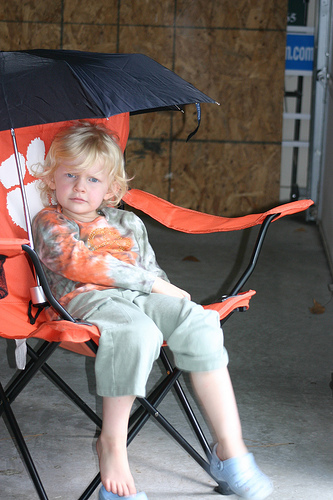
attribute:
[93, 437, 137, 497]
foot — bare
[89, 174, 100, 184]
eye — blue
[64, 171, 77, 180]
eye — blue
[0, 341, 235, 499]
legs — metal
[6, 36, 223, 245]
umbrella — black, open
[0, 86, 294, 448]
chair — folded, orange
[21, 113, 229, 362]
kid — blonde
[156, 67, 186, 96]
wall — brown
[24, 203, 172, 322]
shirt — orange, grey, long-sleeve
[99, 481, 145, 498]
croc — blue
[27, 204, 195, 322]
shirt — orange, gray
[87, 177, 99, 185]
eye — blue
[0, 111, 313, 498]
chair — folding, orange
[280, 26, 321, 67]
sign — blue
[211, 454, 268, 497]
shoe — white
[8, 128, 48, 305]
shaft — silver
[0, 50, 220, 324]
umbrella — black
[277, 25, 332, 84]
sign — white, blue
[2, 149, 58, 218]
paw — white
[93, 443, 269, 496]
shoes — blue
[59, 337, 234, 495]
leg — black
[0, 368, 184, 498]
leg — black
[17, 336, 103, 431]
leg — black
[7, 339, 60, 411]
leg — black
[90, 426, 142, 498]
foot — bare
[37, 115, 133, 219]
hair — blonde